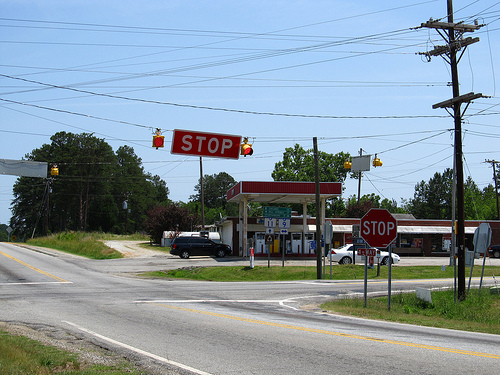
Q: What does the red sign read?
A: Stop.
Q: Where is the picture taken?
A: A gas station.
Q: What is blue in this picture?
A: Sky.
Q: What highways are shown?
A: 9 and 11.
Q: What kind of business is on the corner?
A: A gas station.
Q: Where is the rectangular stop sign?
A: Hanging by wires.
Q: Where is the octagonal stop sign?
A: On two posts by the corner.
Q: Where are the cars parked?
A: At a gas station.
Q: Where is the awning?
A: Over the gas pumps.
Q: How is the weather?
A: Sunny.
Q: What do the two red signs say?
A: Stop.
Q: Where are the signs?
A: Intersection.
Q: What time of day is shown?
A: Afternoon.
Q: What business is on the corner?
A: Gas station.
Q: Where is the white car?
A: At the gas station.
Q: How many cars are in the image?
A: Two.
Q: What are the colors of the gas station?
A: Red & white.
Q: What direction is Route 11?
A: Straight.